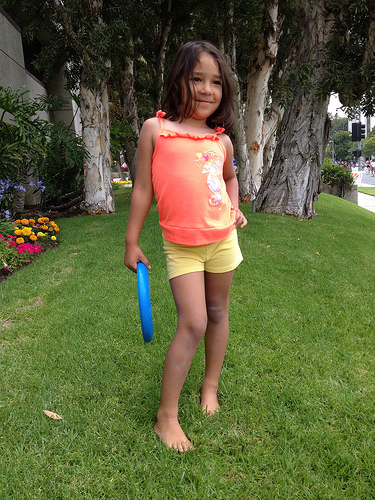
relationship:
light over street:
[351, 121, 367, 142] [352, 168, 374, 184]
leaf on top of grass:
[43, 410, 62, 420] [3, 199, 374, 496]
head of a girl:
[153, 37, 239, 128] [113, 26, 254, 454]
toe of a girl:
[171, 438, 188, 457] [123, 37, 251, 457]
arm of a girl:
[120, 117, 162, 246] [123, 37, 251, 457]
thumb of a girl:
[138, 249, 151, 272] [123, 37, 251, 457]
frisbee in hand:
[113, 254, 186, 337] [70, 220, 173, 253]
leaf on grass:
[40, 401, 63, 427] [256, 406, 340, 487]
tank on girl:
[151, 118, 242, 246] [135, 34, 257, 458]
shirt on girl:
[152, 110, 235, 240] [123, 39, 249, 454]